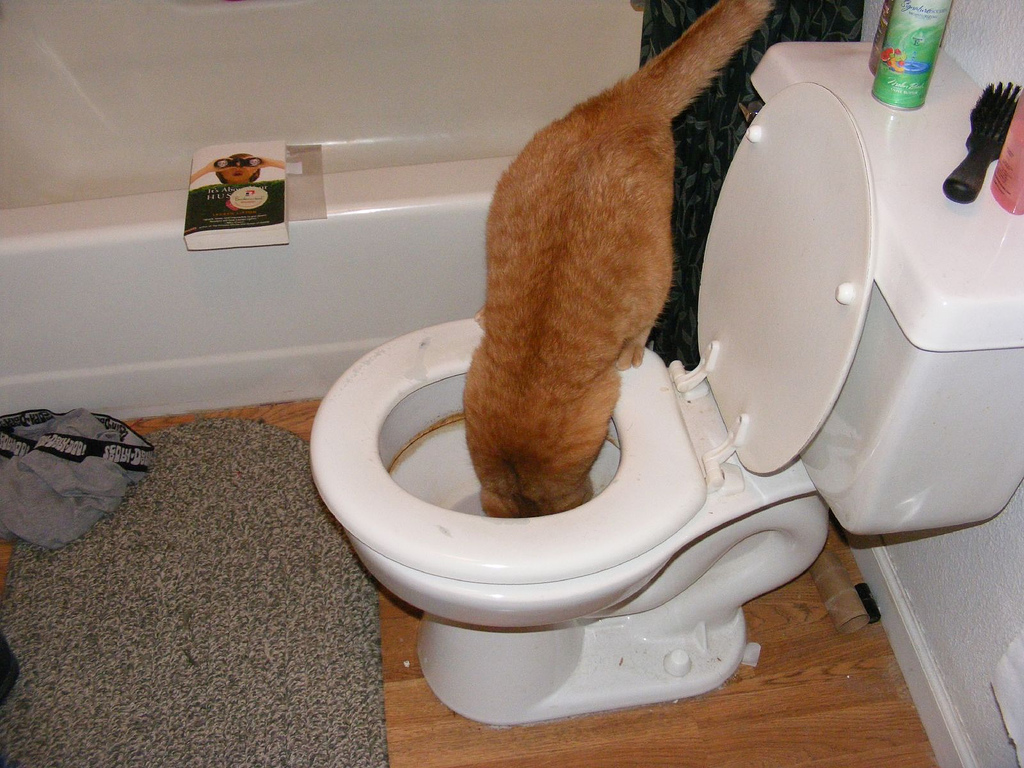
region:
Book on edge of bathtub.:
[189, 142, 287, 237]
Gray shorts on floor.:
[19, 408, 141, 523]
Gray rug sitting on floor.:
[24, 407, 376, 753]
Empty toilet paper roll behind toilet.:
[819, 554, 859, 635]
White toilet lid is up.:
[705, 98, 860, 456]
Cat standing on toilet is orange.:
[490, 114, 655, 484]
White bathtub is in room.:
[36, 24, 594, 296]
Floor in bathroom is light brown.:
[685, 689, 919, 750]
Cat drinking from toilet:
[430, 83, 781, 523]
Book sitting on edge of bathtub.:
[170, 119, 322, 307]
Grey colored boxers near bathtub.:
[13, 379, 166, 617]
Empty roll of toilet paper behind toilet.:
[781, 556, 896, 671]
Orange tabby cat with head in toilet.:
[460, 37, 707, 537]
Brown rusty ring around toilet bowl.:
[382, 383, 478, 513]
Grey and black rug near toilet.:
[53, 420, 329, 756]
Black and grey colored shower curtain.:
[679, 88, 717, 247]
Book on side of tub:
[191, 147, 302, 252]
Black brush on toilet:
[938, 80, 1018, 208]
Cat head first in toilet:
[451, 6, 766, 507]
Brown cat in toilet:
[419, 6, 765, 518]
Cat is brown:
[428, 8, 755, 518]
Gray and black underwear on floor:
[2, 405, 145, 539]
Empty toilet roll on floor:
[816, 541, 871, 644]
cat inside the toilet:
[428, 18, 741, 572]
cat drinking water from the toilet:
[430, 12, 702, 496]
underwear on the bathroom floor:
[0, 398, 152, 548]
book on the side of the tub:
[181, 119, 287, 244]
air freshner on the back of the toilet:
[876, 2, 944, 123]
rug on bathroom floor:
[39, 423, 375, 743]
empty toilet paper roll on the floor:
[807, 549, 864, 630]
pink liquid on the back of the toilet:
[993, 98, 1019, 215]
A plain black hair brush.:
[939, 79, 1017, 204]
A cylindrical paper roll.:
[811, 550, 870, 634]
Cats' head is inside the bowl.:
[411, 474, 607, 539]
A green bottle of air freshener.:
[874, 0, 952, 109]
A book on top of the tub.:
[184, 139, 289, 248]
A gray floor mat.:
[0, 418, 387, 766]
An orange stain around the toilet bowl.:
[383, 407, 622, 474]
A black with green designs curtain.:
[642, 1, 861, 366]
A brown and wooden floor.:
[0, 401, 937, 766]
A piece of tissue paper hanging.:
[987, 628, 1022, 766]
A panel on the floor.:
[322, 633, 912, 719]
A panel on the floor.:
[771, 712, 945, 763]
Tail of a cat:
[645, 4, 763, 104]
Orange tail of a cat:
[653, 3, 770, 111]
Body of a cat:
[468, 126, 675, 477]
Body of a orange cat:
[476, 148, 653, 465]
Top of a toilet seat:
[297, 375, 418, 566]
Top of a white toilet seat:
[299, 364, 424, 571]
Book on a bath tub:
[176, 132, 391, 282]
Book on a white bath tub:
[185, 127, 359, 292]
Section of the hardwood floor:
[793, 658, 902, 754]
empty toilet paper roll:
[820, 550, 875, 643]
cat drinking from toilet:
[464, 66, 690, 534]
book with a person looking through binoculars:
[183, 140, 289, 249]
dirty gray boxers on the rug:
[0, 408, 156, 551]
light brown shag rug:
[78, 600, 319, 747]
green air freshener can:
[870, 0, 956, 115]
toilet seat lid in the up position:
[693, 82, 883, 519]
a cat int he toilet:
[453, 76, 880, 747]